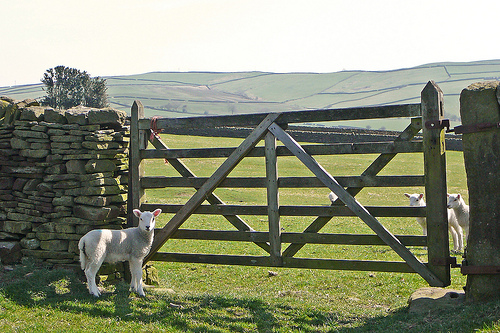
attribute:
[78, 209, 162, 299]
lamb — looking, white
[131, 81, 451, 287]
gate — wooden, brown, wood, large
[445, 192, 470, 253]
lamb — white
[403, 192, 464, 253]
lamb — white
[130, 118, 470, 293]
pasture — green, large, grassy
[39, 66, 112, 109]
tree — leafy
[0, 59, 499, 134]
hillside — green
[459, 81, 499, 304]
wall — stone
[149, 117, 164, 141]
cloth — red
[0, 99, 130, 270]
wall — stone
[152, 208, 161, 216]
ear — pink inside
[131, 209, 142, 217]
ear — pink inside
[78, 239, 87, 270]
tail — white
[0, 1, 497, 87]
sky — cloudy, bright